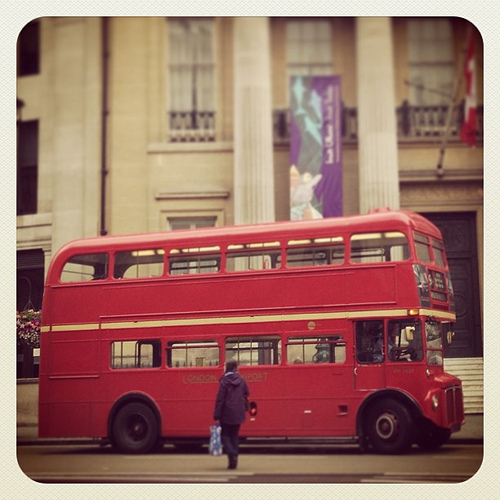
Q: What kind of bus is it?
A: Double decker.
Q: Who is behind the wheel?
A: Bus driver.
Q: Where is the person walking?
A: Across the street.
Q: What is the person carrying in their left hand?
A: A shopping bag.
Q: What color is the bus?
A: Red.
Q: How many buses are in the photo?
A: 1.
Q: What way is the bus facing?
A: Right.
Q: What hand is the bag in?
A: Left.